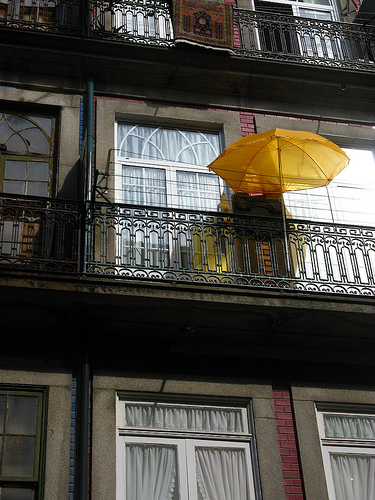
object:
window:
[117, 400, 257, 500]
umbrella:
[206, 127, 352, 194]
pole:
[275, 142, 290, 280]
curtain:
[124, 409, 248, 500]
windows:
[315, 405, 375, 500]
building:
[0, 1, 375, 500]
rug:
[170, 1, 234, 54]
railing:
[0, 191, 374, 302]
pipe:
[72, 81, 93, 500]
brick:
[272, 389, 303, 500]